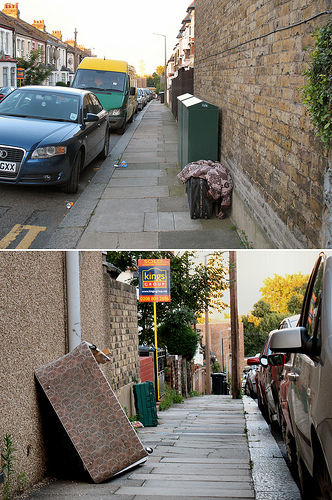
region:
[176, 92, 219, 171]
two green metal bins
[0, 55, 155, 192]
line of parked cars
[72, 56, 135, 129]
green and yellow van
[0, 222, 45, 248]
yellow paint on street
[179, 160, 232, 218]
clothing on top of suitcase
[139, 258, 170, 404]
sign on yellow pole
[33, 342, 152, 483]
furniture leaning against wall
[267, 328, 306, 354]
back of side view mirror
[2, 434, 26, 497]
green weed next to building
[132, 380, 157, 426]
green bin on sidewalk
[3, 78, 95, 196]
A car parked on the side of road.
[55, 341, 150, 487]
A piece of furniture on the sidewalk.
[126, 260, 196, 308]
A blue and orange sign on the sidewalk.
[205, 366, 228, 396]
Garbage bins on the sidewalk.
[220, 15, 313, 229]
A brick building on the side.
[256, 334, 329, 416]
Cars parked along side the road.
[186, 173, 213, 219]
A suitcase on the sidewalk.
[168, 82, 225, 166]
Two green bins on the sidewalk.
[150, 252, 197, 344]
Trees behind the gate.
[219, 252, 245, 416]
A wooden pole on the sidewalk.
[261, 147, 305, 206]
A brick house wall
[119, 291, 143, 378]
A brick house wall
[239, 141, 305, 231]
A brick house wall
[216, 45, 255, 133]
A brick house wall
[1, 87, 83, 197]
A blue saloon car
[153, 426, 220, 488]
A tile roadside pavement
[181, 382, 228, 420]
A tile roadside pavement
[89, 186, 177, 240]
A tile roadside pavement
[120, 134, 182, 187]
A tile roadside pavement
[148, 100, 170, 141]
A tile roadside pavement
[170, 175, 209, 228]
A suitcase on the sidewalk.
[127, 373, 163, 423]
A green box on the wall.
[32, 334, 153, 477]
A piece of furniture leaning against the wall.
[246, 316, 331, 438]
Cars parked along side the sidewalk.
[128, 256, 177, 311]
A blue sign on the yellow pole.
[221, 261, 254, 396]
A tall wooden pole on the side walk.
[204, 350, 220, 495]
Black garbage bin on the sidewalk.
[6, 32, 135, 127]
A van parked on the side of road.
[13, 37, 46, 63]
Windows on the building.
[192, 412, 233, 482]
Cracks on the sidewalk.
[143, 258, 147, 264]
yellow letter on sign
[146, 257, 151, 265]
yellow letter on sign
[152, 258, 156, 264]
yellow letter on sign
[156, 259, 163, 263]
yellow letter on sign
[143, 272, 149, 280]
yellow letter on sign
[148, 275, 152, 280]
yellow letter on sign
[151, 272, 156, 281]
yellow letter on sign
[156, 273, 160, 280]
yellow letter on sign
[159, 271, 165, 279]
yellow letter on sign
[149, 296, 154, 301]
yellow letter on sign